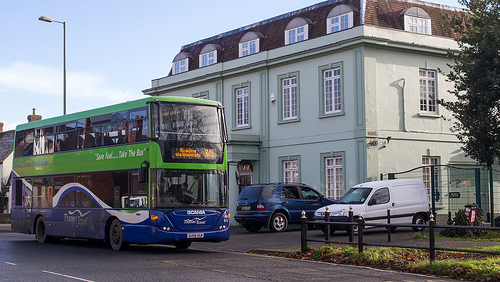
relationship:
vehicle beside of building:
[234, 181, 331, 231] [141, 0, 499, 226]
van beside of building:
[312, 178, 431, 238] [141, 0, 499, 226]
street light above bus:
[36, 16, 55, 26] [12, 96, 234, 254]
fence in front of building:
[299, 208, 500, 264] [141, 0, 499, 226]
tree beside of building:
[433, 1, 499, 174] [141, 0, 499, 226]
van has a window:
[312, 178, 431, 238] [367, 186, 393, 207]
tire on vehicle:
[269, 212, 287, 232] [234, 181, 331, 231]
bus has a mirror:
[12, 96, 234, 254] [137, 158, 150, 187]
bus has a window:
[12, 96, 234, 254] [150, 101, 223, 146]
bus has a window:
[12, 96, 234, 254] [154, 167, 229, 207]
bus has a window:
[12, 96, 234, 254] [14, 106, 150, 158]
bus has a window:
[12, 96, 234, 254] [13, 167, 151, 208]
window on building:
[319, 62, 343, 119] [141, 0, 499, 226]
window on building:
[277, 73, 296, 124] [141, 0, 499, 226]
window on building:
[232, 85, 250, 130] [141, 0, 499, 226]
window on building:
[417, 66, 438, 115] [141, 0, 499, 226]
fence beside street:
[299, 208, 500, 264] [1, 232, 457, 281]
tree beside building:
[433, 1, 499, 174] [141, 0, 499, 226]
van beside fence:
[312, 178, 431, 238] [299, 208, 500, 264]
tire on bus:
[108, 218, 128, 252] [12, 96, 234, 254]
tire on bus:
[33, 214, 48, 246] [12, 96, 234, 254]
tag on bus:
[186, 232, 206, 241] [12, 96, 234, 254]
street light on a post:
[36, 16, 55, 26] [59, 20, 68, 115]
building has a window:
[141, 0, 499, 226] [232, 85, 250, 130]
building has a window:
[141, 0, 499, 226] [277, 73, 296, 124]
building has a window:
[141, 0, 499, 226] [319, 62, 343, 119]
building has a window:
[141, 0, 499, 226] [417, 66, 438, 115]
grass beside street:
[292, 243, 500, 279] [1, 232, 457, 281]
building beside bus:
[141, 0, 499, 226] [12, 96, 234, 254]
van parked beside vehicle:
[312, 178, 431, 238] [234, 181, 331, 231]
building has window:
[141, 0, 499, 226] [417, 66, 438, 115]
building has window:
[141, 0, 499, 226] [319, 62, 343, 119]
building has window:
[141, 0, 499, 226] [277, 73, 296, 124]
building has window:
[141, 0, 499, 226] [232, 85, 250, 130]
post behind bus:
[59, 20, 68, 115] [12, 96, 234, 254]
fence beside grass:
[299, 208, 500, 264] [292, 243, 500, 279]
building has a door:
[141, 0, 499, 226] [447, 167, 479, 226]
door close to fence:
[447, 167, 479, 226] [299, 208, 500, 264]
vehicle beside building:
[234, 181, 331, 231] [141, 0, 499, 226]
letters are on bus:
[94, 145, 145, 162] [12, 96, 234, 254]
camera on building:
[382, 136, 393, 149] [141, 0, 499, 226]